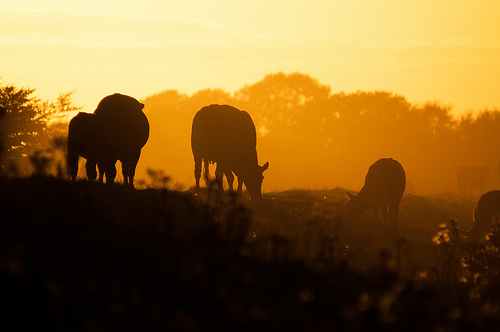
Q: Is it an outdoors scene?
A: Yes, it is outdoors.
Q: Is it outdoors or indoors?
A: It is outdoors.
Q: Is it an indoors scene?
A: No, it is outdoors.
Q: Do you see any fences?
A: No, there are no fences.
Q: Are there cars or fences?
A: No, there are no fences or cars.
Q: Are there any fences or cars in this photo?
A: No, there are no fences or cars.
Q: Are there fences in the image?
A: No, there are no fences.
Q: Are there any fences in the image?
A: No, there are no fences.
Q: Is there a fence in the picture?
A: No, there are no fences.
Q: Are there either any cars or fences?
A: No, there are no fences or cars.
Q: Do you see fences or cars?
A: No, there are no fences or cars.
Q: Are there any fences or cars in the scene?
A: No, there are no fences or cars.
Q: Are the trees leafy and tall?
A: Yes, the trees are leafy and tall.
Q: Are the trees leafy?
A: Yes, the trees are leafy.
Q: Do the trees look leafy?
A: Yes, the trees are leafy.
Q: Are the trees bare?
A: No, the trees are leafy.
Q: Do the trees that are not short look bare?
A: No, the trees are leafy.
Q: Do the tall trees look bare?
A: No, the trees are leafy.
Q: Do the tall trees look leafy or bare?
A: The trees are leafy.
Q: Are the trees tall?
A: Yes, the trees are tall.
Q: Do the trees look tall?
A: Yes, the trees are tall.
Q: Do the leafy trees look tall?
A: Yes, the trees are tall.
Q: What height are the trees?
A: The trees are tall.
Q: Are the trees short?
A: No, the trees are tall.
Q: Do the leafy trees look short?
A: No, the trees are tall.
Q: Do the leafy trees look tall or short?
A: The trees are tall.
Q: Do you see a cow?
A: Yes, there are cows.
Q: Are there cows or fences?
A: Yes, there are cows.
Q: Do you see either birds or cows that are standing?
A: Yes, the cows are standing.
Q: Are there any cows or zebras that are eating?
A: Yes, the cows are eating.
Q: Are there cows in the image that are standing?
A: Yes, there are cows that are standing.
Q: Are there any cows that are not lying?
A: Yes, there are cows that are standing.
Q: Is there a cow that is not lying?
A: Yes, there are cows that are standing.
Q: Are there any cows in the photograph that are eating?
A: Yes, there are cows that are eating.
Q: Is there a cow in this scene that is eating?
A: Yes, there are cows that are eating.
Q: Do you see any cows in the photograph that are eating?
A: Yes, there are cows that are eating.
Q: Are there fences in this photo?
A: No, there are no fences.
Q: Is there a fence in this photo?
A: No, there are no fences.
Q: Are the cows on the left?
A: Yes, the cows are on the left of the image.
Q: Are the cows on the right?
A: No, the cows are on the left of the image.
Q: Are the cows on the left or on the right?
A: The cows are on the left of the image.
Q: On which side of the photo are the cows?
A: The cows are on the left of the image.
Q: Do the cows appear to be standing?
A: Yes, the cows are standing.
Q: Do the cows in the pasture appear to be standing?
A: Yes, the cows are standing.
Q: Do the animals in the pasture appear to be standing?
A: Yes, the cows are standing.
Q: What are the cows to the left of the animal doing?
A: The cows are standing.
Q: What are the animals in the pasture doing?
A: The cows are standing.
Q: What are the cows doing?
A: The cows are standing.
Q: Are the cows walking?
A: No, the cows are standing.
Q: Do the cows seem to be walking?
A: No, the cows are standing.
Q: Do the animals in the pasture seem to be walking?
A: No, the cows are standing.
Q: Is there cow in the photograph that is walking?
A: No, there are cows but they are standing.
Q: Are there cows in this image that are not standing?
A: No, there are cows but they are standing.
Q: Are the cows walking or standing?
A: The cows are standing.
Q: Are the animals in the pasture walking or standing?
A: The cows are standing.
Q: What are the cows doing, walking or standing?
A: The cows are standing.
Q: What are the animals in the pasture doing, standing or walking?
A: The cows are standing.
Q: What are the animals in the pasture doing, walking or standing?
A: The cows are standing.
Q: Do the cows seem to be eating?
A: Yes, the cows are eating.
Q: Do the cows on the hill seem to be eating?
A: Yes, the cows are eating.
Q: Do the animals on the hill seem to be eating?
A: Yes, the cows are eating.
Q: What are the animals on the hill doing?
A: The cows are eating.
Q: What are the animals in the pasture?
A: The animals are cows.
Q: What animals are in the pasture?
A: The animals are cows.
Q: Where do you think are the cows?
A: The cows are in the pasture.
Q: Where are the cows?
A: The cows are in the pasture.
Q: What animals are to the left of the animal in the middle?
A: The animals are cows.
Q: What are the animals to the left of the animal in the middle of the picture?
A: The animals are cows.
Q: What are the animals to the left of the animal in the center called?
A: The animals are cows.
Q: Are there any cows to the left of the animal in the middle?
A: Yes, there are cows to the left of the animal.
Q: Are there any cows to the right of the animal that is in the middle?
A: No, the cows are to the left of the animal.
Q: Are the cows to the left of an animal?
A: Yes, the cows are to the left of an animal.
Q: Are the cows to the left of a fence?
A: No, the cows are to the left of an animal.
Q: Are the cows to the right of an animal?
A: No, the cows are to the left of an animal.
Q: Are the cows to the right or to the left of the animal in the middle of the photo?
A: The cows are to the left of the animal.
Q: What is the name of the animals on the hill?
A: The animals are cows.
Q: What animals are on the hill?
A: The animals are cows.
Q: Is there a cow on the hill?
A: Yes, there are cows on the hill.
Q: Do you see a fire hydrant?
A: No, there are no fire hydrants.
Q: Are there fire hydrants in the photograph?
A: No, there are no fire hydrants.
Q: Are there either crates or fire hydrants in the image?
A: No, there are no fire hydrants or crates.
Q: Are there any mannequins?
A: No, there are no mannequins.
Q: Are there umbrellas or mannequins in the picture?
A: No, there are no mannequins or umbrellas.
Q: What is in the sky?
A: The clouds are in the sky.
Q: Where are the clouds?
A: The clouds are in the sky.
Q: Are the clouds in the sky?
A: Yes, the clouds are in the sky.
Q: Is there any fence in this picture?
A: No, there are no fences.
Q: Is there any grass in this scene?
A: Yes, there is grass.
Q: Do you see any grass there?
A: Yes, there is grass.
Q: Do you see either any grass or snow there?
A: Yes, there is grass.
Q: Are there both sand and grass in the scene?
A: No, there is grass but no sand.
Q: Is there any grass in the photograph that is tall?
A: Yes, there is tall grass.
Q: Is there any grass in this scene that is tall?
A: Yes, there is grass that is tall.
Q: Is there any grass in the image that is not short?
A: Yes, there is tall grass.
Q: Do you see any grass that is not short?
A: Yes, there is tall grass.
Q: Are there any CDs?
A: No, there are no cds.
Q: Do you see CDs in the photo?
A: No, there are no cds.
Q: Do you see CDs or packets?
A: No, there are no CDs or packets.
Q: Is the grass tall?
A: Yes, the grass is tall.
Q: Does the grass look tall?
A: Yes, the grass is tall.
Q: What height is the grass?
A: The grass is tall.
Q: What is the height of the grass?
A: The grass is tall.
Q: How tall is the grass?
A: The grass is tall.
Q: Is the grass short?
A: No, the grass is tall.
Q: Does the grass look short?
A: No, the grass is tall.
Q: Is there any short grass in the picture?
A: No, there is grass but it is tall.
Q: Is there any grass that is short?
A: No, there is grass but it is tall.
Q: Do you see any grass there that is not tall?
A: No, there is grass but it is tall.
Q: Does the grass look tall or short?
A: The grass is tall.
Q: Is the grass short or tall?
A: The grass is tall.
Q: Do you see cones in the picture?
A: No, there are no cones.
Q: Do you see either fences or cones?
A: No, there are no cones or fences.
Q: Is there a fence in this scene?
A: No, there are no fences.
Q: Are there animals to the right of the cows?
A: Yes, there is an animal to the right of the cows.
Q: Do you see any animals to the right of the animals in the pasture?
A: Yes, there is an animal to the right of the cows.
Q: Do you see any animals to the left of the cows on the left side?
A: No, the animal is to the right of the cows.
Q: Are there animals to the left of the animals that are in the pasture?
A: No, the animal is to the right of the cows.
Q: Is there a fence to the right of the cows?
A: No, there is an animal to the right of the cows.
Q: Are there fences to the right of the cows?
A: No, there is an animal to the right of the cows.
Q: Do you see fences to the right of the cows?
A: No, there is an animal to the right of the cows.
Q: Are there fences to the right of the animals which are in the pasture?
A: No, there is an animal to the right of the cows.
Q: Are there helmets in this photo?
A: No, there are no helmets.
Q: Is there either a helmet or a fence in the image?
A: No, there are no helmets or fences.